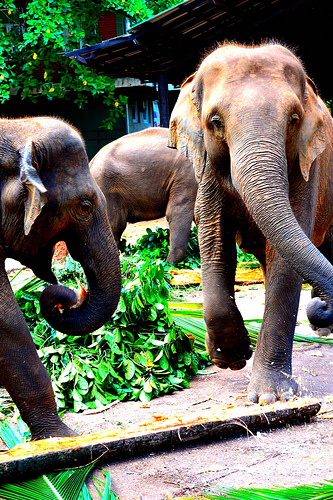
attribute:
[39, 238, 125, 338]
trunk — curls